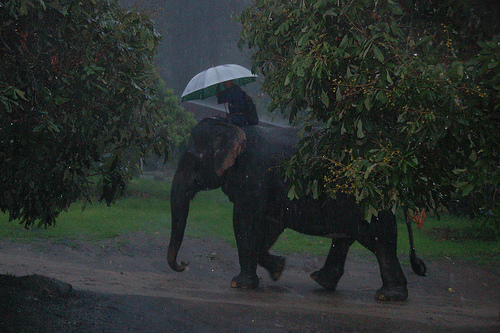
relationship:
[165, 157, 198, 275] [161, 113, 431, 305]
trunk of an elephant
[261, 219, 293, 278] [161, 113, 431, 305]
leg of an elephant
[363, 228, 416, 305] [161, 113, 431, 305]
leg of an elephant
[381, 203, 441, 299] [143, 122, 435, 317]
tail of an elephant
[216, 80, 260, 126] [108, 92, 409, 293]
driver sitting on an elephant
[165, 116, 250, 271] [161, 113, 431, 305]
elephant's head of an elephant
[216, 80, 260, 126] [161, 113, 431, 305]
driver on an elephant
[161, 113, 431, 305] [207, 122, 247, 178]
elephant has ears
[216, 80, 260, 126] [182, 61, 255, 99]
driver holds an umbrella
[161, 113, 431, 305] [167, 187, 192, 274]
elephant has trunk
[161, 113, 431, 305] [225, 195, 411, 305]
elephant has a four legs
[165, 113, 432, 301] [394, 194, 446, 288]
elephant has a tail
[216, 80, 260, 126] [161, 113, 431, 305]
driver riding a elephant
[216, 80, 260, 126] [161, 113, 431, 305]
driver riding an elephant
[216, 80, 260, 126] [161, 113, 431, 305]
driver and an elephant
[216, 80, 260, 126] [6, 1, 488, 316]
driver in rain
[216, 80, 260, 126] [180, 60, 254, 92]
driver holding umbrella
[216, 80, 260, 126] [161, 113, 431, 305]
driver on elephant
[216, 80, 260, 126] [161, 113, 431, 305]
driver riding on elephant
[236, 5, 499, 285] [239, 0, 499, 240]
leaves on tree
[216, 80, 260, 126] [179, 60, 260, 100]
driver holding umbrella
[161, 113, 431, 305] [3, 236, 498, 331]
elephant walking path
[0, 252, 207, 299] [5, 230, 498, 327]
puddle on path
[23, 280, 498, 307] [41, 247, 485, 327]
muddy water on path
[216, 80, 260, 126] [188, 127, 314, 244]
driver sitting near elephant's head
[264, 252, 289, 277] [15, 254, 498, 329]
hoof lifted off ground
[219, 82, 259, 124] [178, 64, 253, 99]
driver wearing umbrella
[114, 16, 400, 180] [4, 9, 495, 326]
rain pouring down in area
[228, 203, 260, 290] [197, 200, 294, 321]
leg of an elephant walking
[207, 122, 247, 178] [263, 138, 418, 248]
ears ear of an elephant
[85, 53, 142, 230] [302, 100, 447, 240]
trees have leaves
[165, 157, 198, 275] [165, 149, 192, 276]
trunk of an elephant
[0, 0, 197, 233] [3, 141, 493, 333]
trees in area